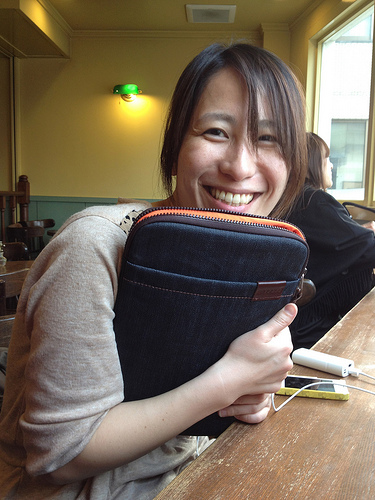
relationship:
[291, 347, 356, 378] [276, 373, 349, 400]
charger for cellphone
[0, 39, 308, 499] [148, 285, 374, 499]
woman sitting at table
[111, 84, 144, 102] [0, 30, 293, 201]
light on wall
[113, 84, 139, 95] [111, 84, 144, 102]
shade on light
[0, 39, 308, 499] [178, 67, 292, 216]
woman has face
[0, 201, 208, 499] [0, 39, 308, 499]
blouse on woman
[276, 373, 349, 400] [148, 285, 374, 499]
cellphone on a table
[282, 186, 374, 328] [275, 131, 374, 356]
poncho on woman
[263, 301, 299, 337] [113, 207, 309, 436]
thumb on tablet case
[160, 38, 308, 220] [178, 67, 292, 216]
hair in face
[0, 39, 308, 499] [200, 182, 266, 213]
woman has grin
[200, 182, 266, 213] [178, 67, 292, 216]
grin on face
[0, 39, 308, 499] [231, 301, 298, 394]
woman has hand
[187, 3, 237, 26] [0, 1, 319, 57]
vent in ceiling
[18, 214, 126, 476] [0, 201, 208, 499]
sleeve on blouse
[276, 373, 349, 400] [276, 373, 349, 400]
cellphone to cellphone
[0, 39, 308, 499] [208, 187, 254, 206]
woman has teeth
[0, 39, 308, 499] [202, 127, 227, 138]
woman has eye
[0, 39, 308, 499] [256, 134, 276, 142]
woman has eye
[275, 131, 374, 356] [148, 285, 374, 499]
woman sitting at table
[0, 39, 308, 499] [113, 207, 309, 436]
woman holding tablet case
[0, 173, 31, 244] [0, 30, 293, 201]
rail on wall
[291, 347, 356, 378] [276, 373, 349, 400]
charger charging cellphone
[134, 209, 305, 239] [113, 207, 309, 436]
lining of a tablet case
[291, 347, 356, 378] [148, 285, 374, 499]
charger resting on table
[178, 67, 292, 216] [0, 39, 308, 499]
face of a woman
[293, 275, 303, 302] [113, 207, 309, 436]
zipper on tablet case